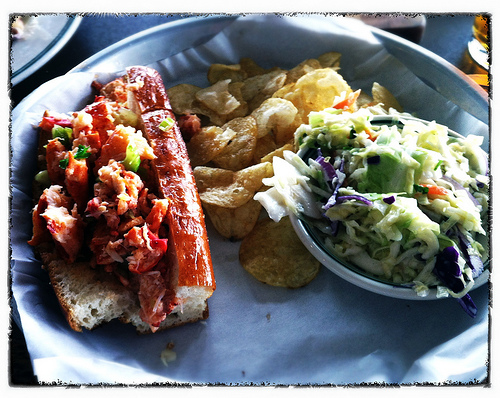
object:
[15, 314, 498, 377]
napkin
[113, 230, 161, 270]
meat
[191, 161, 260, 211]
potato chips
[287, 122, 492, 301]
bowl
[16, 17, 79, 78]
border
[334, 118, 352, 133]
lettuce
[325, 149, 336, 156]
salad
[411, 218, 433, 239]
coleslaw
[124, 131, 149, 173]
vegetables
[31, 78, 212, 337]
bun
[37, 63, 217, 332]
sandwich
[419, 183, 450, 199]
carrot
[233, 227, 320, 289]
potato chip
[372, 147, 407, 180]
cabbage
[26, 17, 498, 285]
table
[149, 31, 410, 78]
liner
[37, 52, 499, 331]
food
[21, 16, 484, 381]
plate